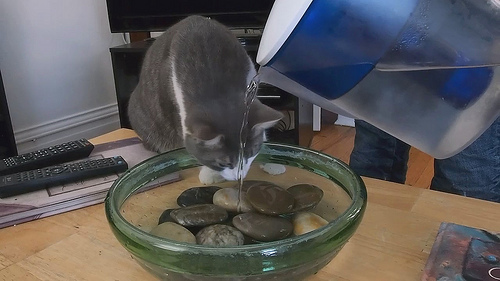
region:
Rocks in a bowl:
[133, 172, 336, 259]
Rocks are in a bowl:
[154, 174, 336, 246]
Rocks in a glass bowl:
[153, 175, 340, 247]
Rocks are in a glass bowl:
[157, 175, 337, 252]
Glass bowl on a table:
[96, 140, 363, 278]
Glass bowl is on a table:
[101, 134, 372, 276]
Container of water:
[241, 0, 498, 163]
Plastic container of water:
[250, 0, 498, 165]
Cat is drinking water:
[121, 11, 288, 186]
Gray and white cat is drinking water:
[125, 10, 280, 180]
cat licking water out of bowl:
[90, 5, 375, 270]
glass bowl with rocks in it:
[100, 140, 365, 280]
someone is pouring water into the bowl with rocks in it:
[225, 0, 492, 201]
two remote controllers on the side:
[2, 123, 137, 190]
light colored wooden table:
[0, 123, 498, 278]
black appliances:
[105, 0, 340, 145]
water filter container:
[245, 3, 496, 153]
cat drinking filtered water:
[121, 10, 269, 180]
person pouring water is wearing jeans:
[340, 67, 497, 199]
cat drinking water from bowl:
[124, 14, 289, 186]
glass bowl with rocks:
[103, 139, 370, 279]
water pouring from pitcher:
[231, 65, 265, 194]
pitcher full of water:
[253, 0, 499, 163]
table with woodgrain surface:
[0, 124, 499, 279]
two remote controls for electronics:
[0, 135, 131, 199]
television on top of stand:
[104, 0, 281, 45]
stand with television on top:
[104, 38, 306, 148]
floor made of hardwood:
[307, 120, 499, 204]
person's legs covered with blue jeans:
[346, 118, 498, 205]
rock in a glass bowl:
[112, 142, 373, 252]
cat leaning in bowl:
[116, 21, 289, 181]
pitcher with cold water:
[243, 5, 493, 160]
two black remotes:
[6, 141, 119, 188]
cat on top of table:
[122, 22, 268, 182]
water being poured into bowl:
[212, 5, 476, 187]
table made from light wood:
[15, 126, 487, 279]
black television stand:
[116, 30, 315, 137]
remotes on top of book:
[2, 140, 164, 218]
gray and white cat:
[110, 13, 262, 180]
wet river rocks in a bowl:
[169, 174, 309, 237]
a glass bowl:
[106, 157, 369, 279]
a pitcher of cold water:
[254, 3, 496, 146]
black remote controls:
[2, 139, 137, 186]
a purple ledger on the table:
[0, 131, 172, 231]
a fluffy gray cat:
[131, 10, 273, 173]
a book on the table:
[425, 217, 494, 279]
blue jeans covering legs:
[351, 122, 496, 189]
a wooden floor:
[323, 123, 356, 153]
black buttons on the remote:
[42, 144, 70, 151]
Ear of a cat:
[181, 113, 224, 148]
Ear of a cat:
[249, 97, 286, 136]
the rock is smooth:
[247, 181, 297, 215]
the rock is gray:
[231, 213, 291, 239]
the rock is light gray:
[211, 187, 256, 212]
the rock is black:
[176, 183, 222, 206]